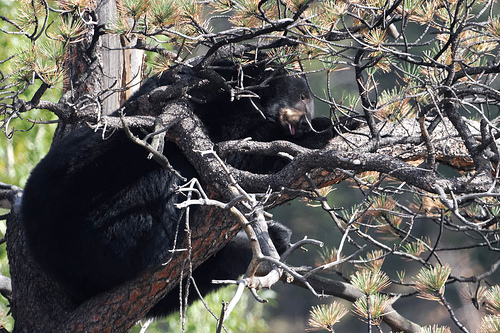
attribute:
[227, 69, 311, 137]
bear — furry, black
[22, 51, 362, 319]
bear — black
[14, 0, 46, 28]
leaves — small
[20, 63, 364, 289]
bear — grizzly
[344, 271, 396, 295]
needles — green, tan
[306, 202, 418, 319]
flowers — green 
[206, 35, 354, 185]
head — round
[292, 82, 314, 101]
eye — beady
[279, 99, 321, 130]
snout — tan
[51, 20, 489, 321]
branches — bare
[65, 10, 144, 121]
stem — big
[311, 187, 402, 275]
bunch — small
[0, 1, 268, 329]
growth — green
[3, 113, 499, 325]
branch — split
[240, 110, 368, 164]
leg — outstretched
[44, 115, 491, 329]
branch — large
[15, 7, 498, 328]
leaves — dried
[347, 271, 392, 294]
leaves — small